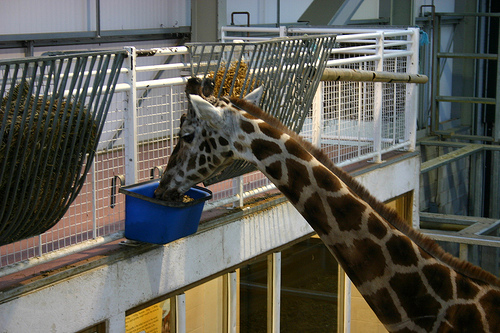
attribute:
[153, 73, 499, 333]
giraffe — drinking, brown, eating, yellow, spotted, white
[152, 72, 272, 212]
head — brown, white, spotted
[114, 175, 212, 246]
container — blue, plastic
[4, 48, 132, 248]
container — metal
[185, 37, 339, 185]
container — metal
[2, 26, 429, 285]
fence — metal, white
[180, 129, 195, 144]
eye — black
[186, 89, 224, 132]
ear — white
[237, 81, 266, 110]
ear — white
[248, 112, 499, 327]
neck — long, brown, white, spotted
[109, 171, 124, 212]
hook — metal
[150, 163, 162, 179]
hook — metal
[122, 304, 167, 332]
sign — orange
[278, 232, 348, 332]
window — clear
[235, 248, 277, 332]
window — clear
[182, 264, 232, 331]
window — clear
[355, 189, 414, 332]
window — clear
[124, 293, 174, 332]
window — clear